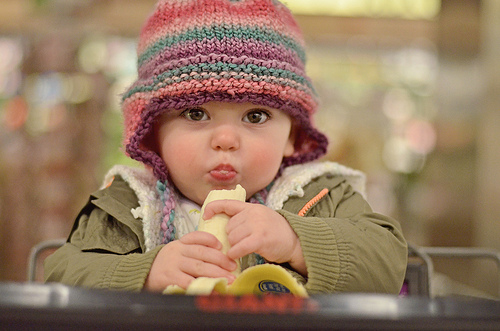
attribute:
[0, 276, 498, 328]
bar — silver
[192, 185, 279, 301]
banana — yellow 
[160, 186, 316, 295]
banana — peeled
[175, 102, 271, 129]
eyes — brown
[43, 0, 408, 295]
child — staring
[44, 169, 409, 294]
jacket — green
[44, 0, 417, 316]
girl — little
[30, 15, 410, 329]
chld — small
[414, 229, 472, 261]
bar — plastic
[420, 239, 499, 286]
bar — metal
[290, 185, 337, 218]
zipper — orange 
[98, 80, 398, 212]
purple beanie — green, pink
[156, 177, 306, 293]
banana — peeled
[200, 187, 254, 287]
banana — yellow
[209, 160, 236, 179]
lips — red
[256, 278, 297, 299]
sticker — blue